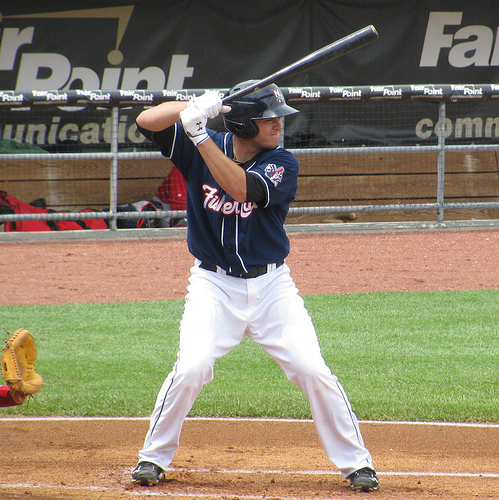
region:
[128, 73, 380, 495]
a man playing baseball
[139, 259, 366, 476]
a pair of white baseball pants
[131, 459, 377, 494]
black athletic shoes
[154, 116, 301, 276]
a blue baseball jersey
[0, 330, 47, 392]
a brown catcher's mitt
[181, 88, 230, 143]
a pair of white baseball gloves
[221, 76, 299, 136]
a black baseball helmet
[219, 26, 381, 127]
a black baseball bat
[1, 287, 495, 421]
a grassy area of the baseball field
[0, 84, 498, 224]
a padded fence behind the player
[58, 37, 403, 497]
A batter is on the baseball field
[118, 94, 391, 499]
There is one person in the photo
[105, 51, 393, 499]
The person has a bat in his hand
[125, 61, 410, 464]
The batter is wearing white pants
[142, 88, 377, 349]
The batter is wearing a blue shirt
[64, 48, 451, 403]
Photo was taken during the day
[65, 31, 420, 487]
Photo was taken outside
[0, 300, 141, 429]
A mitt is in the photo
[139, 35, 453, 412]
The baseball player has white pants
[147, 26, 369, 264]
The baseball players is wearing a helmet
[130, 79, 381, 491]
Baseball player at bat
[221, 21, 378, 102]
Black bat held by a player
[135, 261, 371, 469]
White pants worn by baseball player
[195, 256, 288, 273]
Black belt on baseball player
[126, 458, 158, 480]
Black cleated shoe worn by baseball player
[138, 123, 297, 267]
Blue jersey on baseball player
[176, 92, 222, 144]
White batting gloves on a player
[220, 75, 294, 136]
Black baseball helmet on a player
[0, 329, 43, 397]
Gold catchers glove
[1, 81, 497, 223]
Screen in front of a baseball dugout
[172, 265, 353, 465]
baseball player wearing white pants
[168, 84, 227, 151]
baseball player wearing white gloves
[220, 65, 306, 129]
baseball player wearing blue helmet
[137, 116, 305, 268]
baseball player wearing red, white and blue shirt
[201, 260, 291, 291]
baseball player wearing black belt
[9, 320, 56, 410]
brown glove held by catcher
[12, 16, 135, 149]
blue and white sign in dugout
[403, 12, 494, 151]
blue and white sign in dugout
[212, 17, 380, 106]
black bat held by batter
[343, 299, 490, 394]
green grass on baseball field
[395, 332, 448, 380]
part of some grass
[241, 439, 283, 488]
part of the ground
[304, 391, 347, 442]
part of a trouser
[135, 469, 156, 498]
part of a shoe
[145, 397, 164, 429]
part of a line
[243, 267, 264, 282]
part of a belt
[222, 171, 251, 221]
part of an elbow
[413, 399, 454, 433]
edge of the grass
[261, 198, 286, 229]
part of a top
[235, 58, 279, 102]
handle of a club